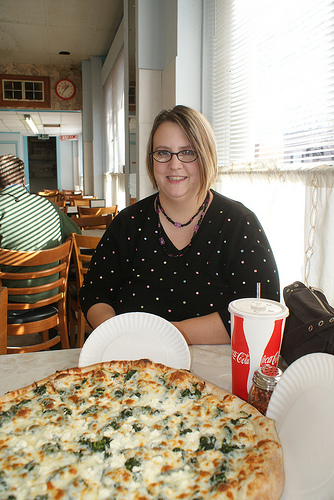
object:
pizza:
[0, 346, 290, 497]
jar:
[246, 359, 282, 417]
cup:
[221, 281, 291, 416]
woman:
[76, 96, 285, 349]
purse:
[275, 275, 333, 369]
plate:
[78, 303, 194, 371]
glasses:
[149, 146, 201, 167]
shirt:
[76, 188, 283, 337]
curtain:
[208, 166, 333, 301]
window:
[201, 1, 334, 314]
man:
[0, 148, 66, 330]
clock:
[54, 75, 78, 102]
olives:
[197, 432, 216, 455]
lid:
[226, 295, 291, 325]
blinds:
[202, 1, 333, 174]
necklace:
[156, 191, 210, 230]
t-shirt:
[0, 177, 65, 317]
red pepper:
[249, 387, 272, 416]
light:
[24, 116, 39, 137]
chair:
[0, 234, 75, 357]